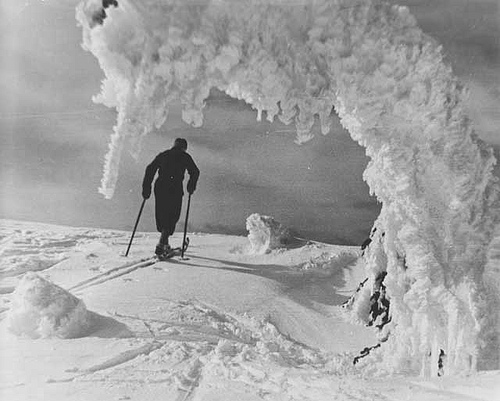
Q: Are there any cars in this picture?
A: No, there are no cars.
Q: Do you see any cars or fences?
A: No, there are no cars or fences.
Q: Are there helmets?
A: No, there are no helmets.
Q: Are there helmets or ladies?
A: No, there are no helmets or ladies.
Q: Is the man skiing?
A: Yes, the man is skiing.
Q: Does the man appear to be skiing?
A: Yes, the man is skiing.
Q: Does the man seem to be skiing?
A: Yes, the man is skiing.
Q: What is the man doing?
A: The man is skiing.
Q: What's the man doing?
A: The man is skiing.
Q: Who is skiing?
A: The man is skiing.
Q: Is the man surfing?
A: No, the man is skiing.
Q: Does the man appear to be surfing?
A: No, the man is skiing.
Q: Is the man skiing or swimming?
A: The man is skiing.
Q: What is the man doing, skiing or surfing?
A: The man is skiing.